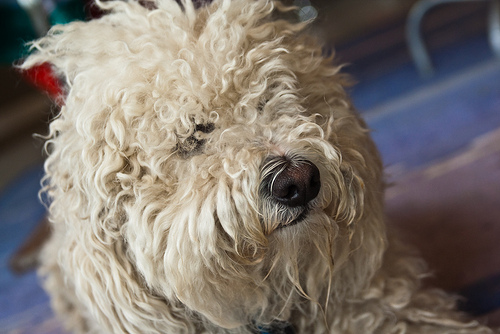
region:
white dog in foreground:
[1, 7, 426, 300]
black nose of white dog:
[220, 156, 320, 212]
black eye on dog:
[166, 111, 230, 146]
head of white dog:
[38, 22, 339, 253]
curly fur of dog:
[18, 20, 115, 91]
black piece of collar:
[226, 275, 352, 332]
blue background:
[379, 78, 499, 212]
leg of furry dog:
[307, 244, 467, 329]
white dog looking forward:
[57, 56, 353, 243]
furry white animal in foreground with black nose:
[0, 12, 380, 304]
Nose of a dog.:
[255, 157, 335, 210]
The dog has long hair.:
[34, 10, 451, 332]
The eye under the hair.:
[158, 115, 221, 157]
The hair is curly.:
[41, 19, 393, 314]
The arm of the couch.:
[397, 0, 498, 78]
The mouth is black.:
[269, 203, 317, 229]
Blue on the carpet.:
[397, 95, 461, 133]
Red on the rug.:
[436, 183, 499, 270]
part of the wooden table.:
[7, 204, 52, 274]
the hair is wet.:
[248, 217, 331, 322]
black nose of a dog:
[260, 157, 337, 216]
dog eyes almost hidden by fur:
[154, 80, 335, 151]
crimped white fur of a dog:
[23, 11, 165, 98]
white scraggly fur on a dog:
[37, 131, 161, 324]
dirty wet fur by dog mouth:
[283, 216, 359, 286]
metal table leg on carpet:
[391, 9, 462, 111]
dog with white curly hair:
[21, 5, 451, 316]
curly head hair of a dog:
[116, 53, 213, 98]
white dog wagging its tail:
[33, 14, 436, 309]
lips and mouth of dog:
[277, 194, 332, 245]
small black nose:
[253, 142, 344, 245]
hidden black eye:
[143, 87, 232, 164]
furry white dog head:
[24, 17, 409, 304]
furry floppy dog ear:
[19, 58, 178, 324]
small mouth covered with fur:
[253, 194, 355, 240]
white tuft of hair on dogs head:
[23, 5, 343, 148]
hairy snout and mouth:
[200, 135, 398, 291]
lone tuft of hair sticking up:
[18, 23, 91, 88]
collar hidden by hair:
[183, 266, 364, 331]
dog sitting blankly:
[19, 26, 454, 313]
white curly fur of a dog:
[187, 34, 246, 86]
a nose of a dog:
[258, 152, 331, 209]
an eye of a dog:
[164, 105, 216, 162]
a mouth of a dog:
[263, 198, 344, 240]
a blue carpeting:
[418, 105, 461, 147]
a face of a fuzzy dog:
[123, 47, 364, 274]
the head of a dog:
[34, 17, 401, 317]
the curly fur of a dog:
[49, 137, 101, 215]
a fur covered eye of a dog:
[155, 89, 217, 166]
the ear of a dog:
[26, 30, 108, 77]